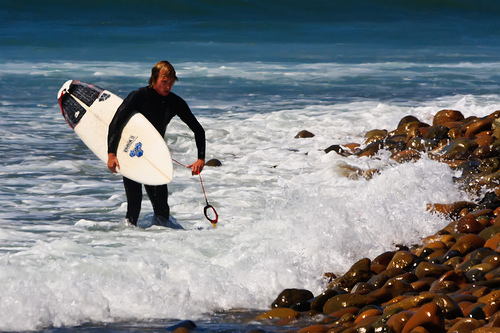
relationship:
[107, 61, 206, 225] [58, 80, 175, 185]
man holding surfboard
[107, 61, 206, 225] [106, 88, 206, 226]
man wearing suit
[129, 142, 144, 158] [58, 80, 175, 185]
logo on surfboard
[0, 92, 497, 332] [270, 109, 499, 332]
foam on shore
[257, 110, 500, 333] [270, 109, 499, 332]
rocks on shore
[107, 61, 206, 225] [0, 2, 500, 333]
man in ocean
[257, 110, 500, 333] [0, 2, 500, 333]
rocks next to ocean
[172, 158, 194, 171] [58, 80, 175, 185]
strap on surfboard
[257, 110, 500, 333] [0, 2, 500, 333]
rocks are near ocean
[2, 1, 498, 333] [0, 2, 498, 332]
photo in daytime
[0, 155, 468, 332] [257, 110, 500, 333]
wave hitting rocks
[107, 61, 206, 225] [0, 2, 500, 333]
man leaving ocean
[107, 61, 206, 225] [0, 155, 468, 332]
man walking into wave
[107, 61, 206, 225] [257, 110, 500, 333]
man walking towards rocks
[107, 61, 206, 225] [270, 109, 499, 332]
man walking to shore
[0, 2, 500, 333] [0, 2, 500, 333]
ocean in ocean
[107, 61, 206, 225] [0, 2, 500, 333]
man walking in ocean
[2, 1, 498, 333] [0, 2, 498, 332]
photo taken during daytime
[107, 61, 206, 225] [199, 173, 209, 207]
man has string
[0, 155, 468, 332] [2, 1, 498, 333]
wave in photo